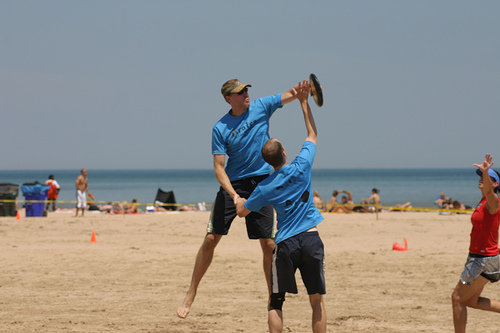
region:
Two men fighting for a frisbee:
[191, 54, 356, 306]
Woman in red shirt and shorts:
[443, 157, 495, 327]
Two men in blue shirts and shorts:
[189, 75, 363, 311]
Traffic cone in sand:
[69, 219, 131, 261]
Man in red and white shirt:
[41, 169, 68, 215]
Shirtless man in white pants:
[68, 162, 98, 222]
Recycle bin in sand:
[20, 176, 57, 226]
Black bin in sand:
[0, 173, 22, 248]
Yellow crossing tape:
[100, 177, 200, 224]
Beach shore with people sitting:
[331, 137, 445, 232]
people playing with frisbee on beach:
[134, 56, 376, 307]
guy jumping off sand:
[170, 67, 304, 332]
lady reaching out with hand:
[426, 129, 498, 331]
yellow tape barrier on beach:
[10, 180, 189, 227]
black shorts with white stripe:
[254, 228, 353, 323]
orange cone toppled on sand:
[380, 230, 432, 267]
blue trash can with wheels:
[12, 170, 60, 236]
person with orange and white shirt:
[33, 165, 69, 225]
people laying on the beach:
[327, 180, 478, 220]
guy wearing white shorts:
[67, 154, 124, 224]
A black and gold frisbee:
[307, 70, 332, 109]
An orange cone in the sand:
[87, 228, 102, 246]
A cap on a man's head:
[213, 76, 259, 99]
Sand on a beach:
[130, 223, 175, 255]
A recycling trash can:
[16, 179, 54, 218]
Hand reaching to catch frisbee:
[475, 141, 497, 191]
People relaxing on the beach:
[329, 189, 474, 213]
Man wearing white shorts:
[70, 165, 94, 219]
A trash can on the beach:
[1, 179, 19, 231]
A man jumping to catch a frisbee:
[170, 69, 267, 329]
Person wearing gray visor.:
[217, 75, 284, 112]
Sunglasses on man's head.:
[236, 75, 255, 100]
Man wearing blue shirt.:
[223, 114, 277, 189]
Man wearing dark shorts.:
[211, 189, 291, 253]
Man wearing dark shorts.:
[273, 248, 338, 280]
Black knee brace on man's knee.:
[259, 274, 289, 313]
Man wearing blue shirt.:
[254, 158, 327, 233]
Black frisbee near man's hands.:
[300, 60, 334, 111]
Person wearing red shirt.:
[458, 200, 492, 231]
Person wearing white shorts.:
[68, 183, 115, 232]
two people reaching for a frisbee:
[170, 70, 339, 330]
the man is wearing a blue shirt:
[209, 96, 286, 178]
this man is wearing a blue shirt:
[245, 140, 329, 247]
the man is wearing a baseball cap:
[212, 70, 253, 100]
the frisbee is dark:
[305, 72, 325, 109]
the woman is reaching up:
[449, 144, 499, 331]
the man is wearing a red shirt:
[463, 191, 497, 255]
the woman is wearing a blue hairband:
[473, 168, 498, 182]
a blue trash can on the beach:
[18, 176, 46, 218]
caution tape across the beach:
[3, 201, 470, 213]